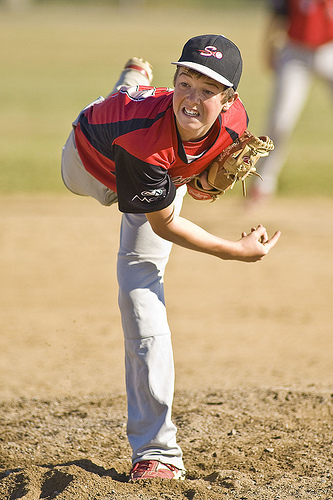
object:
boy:
[60, 34, 286, 481]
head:
[171, 36, 243, 133]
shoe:
[126, 457, 187, 486]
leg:
[116, 189, 188, 482]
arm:
[116, 145, 238, 263]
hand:
[236, 222, 283, 263]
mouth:
[177, 106, 206, 121]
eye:
[177, 81, 191, 90]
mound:
[0, 391, 332, 500]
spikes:
[123, 56, 155, 84]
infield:
[1, 1, 331, 499]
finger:
[261, 230, 286, 253]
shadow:
[0, 458, 129, 499]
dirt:
[0, 389, 330, 497]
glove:
[186, 135, 273, 203]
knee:
[116, 271, 166, 323]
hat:
[172, 36, 242, 90]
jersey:
[74, 83, 250, 214]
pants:
[60, 87, 187, 471]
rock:
[228, 427, 238, 437]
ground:
[0, 195, 331, 498]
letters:
[129, 187, 162, 205]